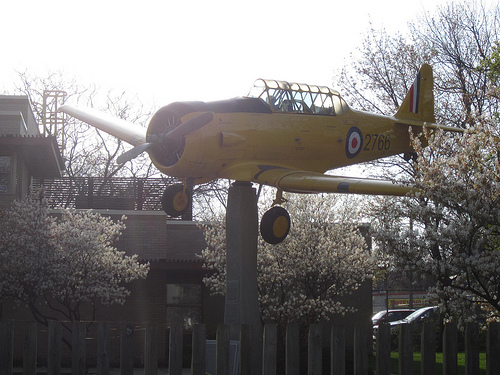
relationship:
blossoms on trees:
[372, 119, 499, 317] [2, 7, 499, 324]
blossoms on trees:
[194, 184, 377, 320] [2, 7, 499, 324]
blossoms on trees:
[3, 185, 154, 305] [2, 7, 499, 324]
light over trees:
[41, 0, 287, 79] [0, 0, 499, 352]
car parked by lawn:
[371, 303, 418, 333] [377, 350, 490, 373]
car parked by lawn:
[371, 306, 500, 349] [377, 350, 490, 373]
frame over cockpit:
[243, 75, 351, 117] [250, 97, 364, 176]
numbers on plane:
[359, 128, 399, 158] [54, 55, 476, 241]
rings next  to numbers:
[340, 123, 366, 159] [359, 128, 399, 158]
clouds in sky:
[37, 46, 276, 80] [29, 7, 444, 108]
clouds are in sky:
[12, 0, 472, 90] [8, 0, 488, 128]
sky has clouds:
[8, 0, 488, 128] [12, 0, 472, 90]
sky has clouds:
[4, 0, 330, 55] [12, 15, 135, 73]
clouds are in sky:
[12, 15, 135, 73] [4, 0, 330, 55]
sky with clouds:
[0, 21, 496, 243] [57, 33, 331, 75]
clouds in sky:
[5, 0, 428, 86] [30, 53, 356, 91]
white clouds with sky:
[330, 2, 358, 29] [0, 0, 396, 110]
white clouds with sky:
[260, 38, 289, 62] [0, 0, 396, 110]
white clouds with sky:
[155, 35, 180, 56] [0, 0, 396, 110]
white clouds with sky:
[110, 8, 142, 48] [0, 0, 396, 110]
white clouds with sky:
[30, 20, 64, 47] [0, 0, 396, 110]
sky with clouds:
[3, 17, 498, 224] [87, 0, 364, 87]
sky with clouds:
[3, 17, 498, 224] [33, 24, 371, 89]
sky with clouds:
[8, 0, 499, 88] [24, 10, 362, 79]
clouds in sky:
[24, 10, 362, 79] [8, 0, 499, 88]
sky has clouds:
[11, 0, 497, 215] [37, 4, 349, 76]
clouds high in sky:
[54, 16, 151, 53] [11, 7, 483, 80]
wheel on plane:
[259, 202, 293, 248] [90, 57, 481, 248]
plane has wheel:
[90, 57, 481, 248] [259, 202, 293, 248]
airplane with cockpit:
[54, 63, 476, 245] [256, 76, 343, 116]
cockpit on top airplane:
[256, 76, 343, 116] [54, 63, 476, 245]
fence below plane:
[2, 315, 499, 372] [67, 58, 442, 260]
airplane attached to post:
[46, 54, 448, 259] [228, 184, 251, 373]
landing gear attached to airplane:
[258, 195, 300, 244] [54, 63, 476, 245]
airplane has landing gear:
[54, 63, 476, 245] [258, 195, 300, 244]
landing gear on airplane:
[156, 177, 203, 214] [54, 63, 476, 245]